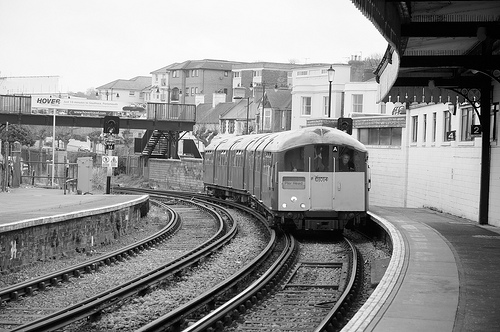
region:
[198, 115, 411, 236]
6 car train on a railroad track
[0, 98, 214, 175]
large walk across over the tracks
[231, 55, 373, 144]
street lights in the background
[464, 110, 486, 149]
the number 2 on a information sign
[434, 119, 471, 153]
the number 4 on a information sign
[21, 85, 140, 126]
advertisement with the letter h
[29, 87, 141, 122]
advertisement with the letter o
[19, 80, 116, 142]
advertisement with the letter v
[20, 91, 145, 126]
advertisement with the letter e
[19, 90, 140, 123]
advertisement with the letter r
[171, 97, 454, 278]
Train on the tracks.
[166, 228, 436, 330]
Steel tracks under the train.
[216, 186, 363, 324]
Gravel under the train.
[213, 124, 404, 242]
Windows on the train.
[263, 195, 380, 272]
Wheels on the train.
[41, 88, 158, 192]
Buildings in the background.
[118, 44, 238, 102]
Windows on the building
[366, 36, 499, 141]
Awning over the track.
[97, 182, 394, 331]
Steel rails on the tracks.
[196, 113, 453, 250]
Passenger train on the tracks.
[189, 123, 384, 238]
train on the tracks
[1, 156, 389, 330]
two sets of parallel train tracks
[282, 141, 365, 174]
windows on the front of the train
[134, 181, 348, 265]
train tracks are curved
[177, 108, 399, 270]
train turning a corner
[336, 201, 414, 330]
line painted along the side of the train tracks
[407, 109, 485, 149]
windows on the side of the building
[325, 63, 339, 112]
tall lamp post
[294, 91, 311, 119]
window on the side of the building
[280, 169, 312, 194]
sign on the front of the train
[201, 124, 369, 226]
train coming into the station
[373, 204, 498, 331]
platform beside the train tracks on right side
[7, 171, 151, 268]
train platform on the left side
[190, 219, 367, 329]
tracks train is traveling on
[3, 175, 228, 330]
train tracks not in use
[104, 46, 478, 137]
houses on the right side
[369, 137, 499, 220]
wall along the train platform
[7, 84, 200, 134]
bridge over the train tracks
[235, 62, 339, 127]
street lights with lamps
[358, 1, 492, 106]
shelter over train platform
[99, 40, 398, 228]
Buildings in the background.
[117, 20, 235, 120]
windows on the buildings.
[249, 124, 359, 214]
Lights on the train.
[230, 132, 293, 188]
Windows on the train.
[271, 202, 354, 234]
Wheels on the train.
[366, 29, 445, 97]
Awning over the station.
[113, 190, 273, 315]
Gravel by the tracks.